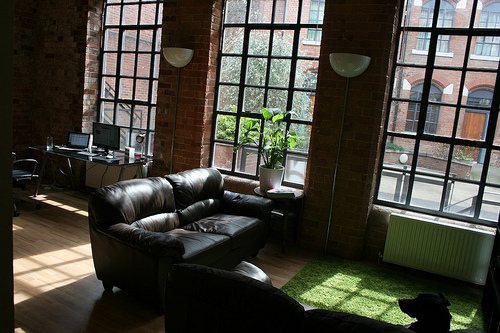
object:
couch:
[87, 167, 275, 307]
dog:
[397, 291, 453, 333]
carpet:
[278, 251, 485, 332]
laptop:
[54, 131, 92, 153]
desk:
[32, 144, 152, 197]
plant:
[232, 108, 299, 170]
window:
[203, 1, 327, 190]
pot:
[258, 165, 285, 193]